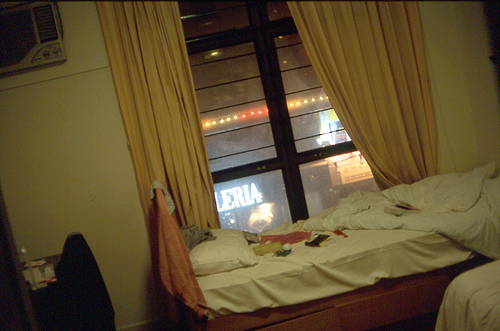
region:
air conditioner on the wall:
[2, 5, 71, 81]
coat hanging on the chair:
[52, 228, 120, 326]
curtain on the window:
[120, 44, 183, 131]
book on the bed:
[302, 228, 334, 256]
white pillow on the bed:
[202, 248, 240, 266]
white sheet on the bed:
[426, 185, 458, 214]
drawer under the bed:
[274, 312, 339, 329]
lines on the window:
[203, 71, 250, 117]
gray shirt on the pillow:
[182, 221, 216, 244]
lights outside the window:
[212, 105, 269, 127]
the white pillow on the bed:
[187, 225, 251, 277]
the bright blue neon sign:
[213, 178, 262, 212]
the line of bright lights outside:
[199, 88, 336, 133]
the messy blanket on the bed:
[282, 168, 496, 251]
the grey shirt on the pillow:
[181, 220, 207, 245]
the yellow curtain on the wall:
[98, 3, 218, 235]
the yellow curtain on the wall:
[290, 3, 435, 182]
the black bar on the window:
[199, 123, 277, 138]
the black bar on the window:
[205, 144, 283, 160]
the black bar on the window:
[290, 103, 342, 118]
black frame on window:
[172, 5, 357, 228]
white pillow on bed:
[170, 209, 270, 301]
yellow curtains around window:
[111, 24, 418, 219]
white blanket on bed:
[325, 177, 475, 266]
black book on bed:
[302, 230, 344, 262]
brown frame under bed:
[312, 266, 475, 328]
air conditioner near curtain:
[0, 16, 71, 65]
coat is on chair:
[55, 221, 112, 326]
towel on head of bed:
[144, 175, 197, 325]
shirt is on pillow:
[182, 202, 217, 264]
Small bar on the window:
[208, 151, 255, 164]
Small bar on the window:
[200, 124, 260, 138]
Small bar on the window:
[200, 103, 262, 115]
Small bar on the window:
[190, 81, 260, 89]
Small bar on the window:
[180, 50, 259, 71]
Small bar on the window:
[271, 41, 317, 49]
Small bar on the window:
[273, 59, 322, 75]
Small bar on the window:
[283, 83, 329, 97]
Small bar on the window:
[289, 99, 337, 123]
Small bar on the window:
[288, 129, 363, 144]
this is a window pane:
[169, 43, 289, 183]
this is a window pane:
[272, 19, 352, 147]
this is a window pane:
[288, 129, 389, 219]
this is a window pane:
[207, 163, 299, 245]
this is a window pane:
[183, 2, 260, 45]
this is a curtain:
[97, 3, 223, 238]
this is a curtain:
[285, 4, 480, 186]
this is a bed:
[155, 163, 492, 299]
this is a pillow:
[187, 189, 270, 290]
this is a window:
[138, 6, 485, 266]